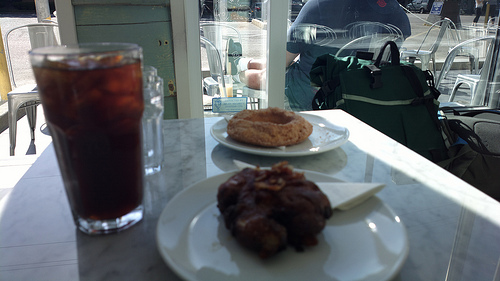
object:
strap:
[375, 40, 401, 68]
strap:
[402, 64, 442, 101]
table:
[0, 109, 499, 280]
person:
[285, 0, 415, 111]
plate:
[209, 112, 350, 157]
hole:
[167, 80, 175, 95]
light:
[189, 216, 244, 278]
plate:
[154, 167, 411, 281]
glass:
[141, 65, 165, 177]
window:
[289, 0, 499, 116]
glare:
[286, 20, 404, 54]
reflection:
[287, 21, 404, 52]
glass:
[283, 0, 499, 110]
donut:
[226, 106, 313, 147]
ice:
[52, 52, 124, 69]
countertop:
[0, 109, 499, 281]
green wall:
[73, 0, 184, 120]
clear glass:
[142, 67, 164, 175]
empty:
[141, 66, 165, 176]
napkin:
[311, 182, 387, 212]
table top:
[0, 109, 499, 281]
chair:
[402, 16, 451, 76]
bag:
[308, 41, 450, 164]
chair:
[433, 18, 500, 107]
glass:
[26, 42, 146, 237]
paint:
[74, 0, 181, 121]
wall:
[58, 0, 206, 124]